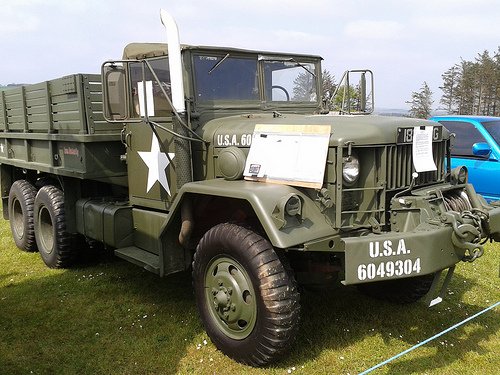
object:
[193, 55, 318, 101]
windshield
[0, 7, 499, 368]
lorry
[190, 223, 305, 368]
wheel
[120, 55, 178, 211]
door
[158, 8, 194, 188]
chimney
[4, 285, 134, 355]
grass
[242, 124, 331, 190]
flyer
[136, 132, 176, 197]
emblem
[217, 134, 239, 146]
usa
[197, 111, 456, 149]
hood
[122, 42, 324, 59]
roof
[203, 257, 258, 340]
hubcaps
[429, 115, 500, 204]
truck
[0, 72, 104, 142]
bed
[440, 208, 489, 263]
chain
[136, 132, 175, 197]
star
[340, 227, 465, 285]
bumper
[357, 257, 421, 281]
numbers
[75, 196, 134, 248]
tank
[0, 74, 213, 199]
side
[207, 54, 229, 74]
wipers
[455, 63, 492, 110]
trees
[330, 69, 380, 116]
distance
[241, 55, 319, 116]
driving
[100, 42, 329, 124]
cab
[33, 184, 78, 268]
tires